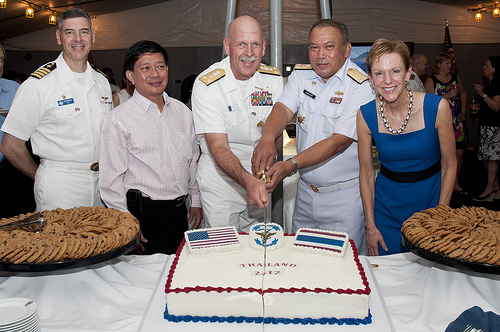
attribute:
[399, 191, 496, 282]
platter — large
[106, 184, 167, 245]
pants — black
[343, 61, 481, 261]
dress — black, blue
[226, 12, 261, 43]
head — bald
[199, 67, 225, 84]
patch — brown, shoulder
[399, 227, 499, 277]
plate — large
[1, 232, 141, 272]
plate — large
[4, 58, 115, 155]
shirt — white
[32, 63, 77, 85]
military patch — black, gold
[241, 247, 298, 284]
lettering — red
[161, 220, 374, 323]
cake — large, red, white , blue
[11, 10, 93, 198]
pants — white 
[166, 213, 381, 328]
cake — cut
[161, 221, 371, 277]
cake — white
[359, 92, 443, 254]
dress — blue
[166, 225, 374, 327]
cake — sheet cake, red, white , blue 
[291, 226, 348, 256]
flag — blue, red, white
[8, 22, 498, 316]
people — smiling 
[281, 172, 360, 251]
pants — white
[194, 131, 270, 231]
pants — white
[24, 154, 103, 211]
pants — white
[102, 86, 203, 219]
shirt — pink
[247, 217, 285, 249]
logo — blue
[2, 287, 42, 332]
plates — white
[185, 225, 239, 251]
flag — American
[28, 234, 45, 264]
cookie — chocolate chip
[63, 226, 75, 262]
cookie — chocolate chip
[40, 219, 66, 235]
cookie — chocolate chip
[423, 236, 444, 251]
cookie — chocolate chip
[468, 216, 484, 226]
cookie — chocolate chip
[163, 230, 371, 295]
border — red